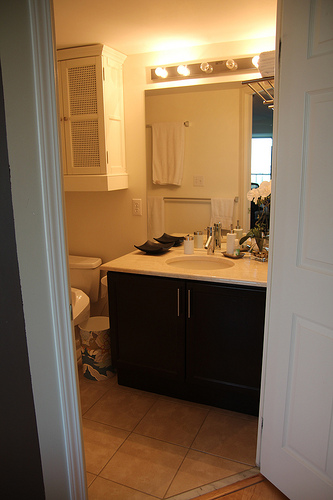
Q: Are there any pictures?
A: No, there are no pictures.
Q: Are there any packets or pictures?
A: No, there are no pictures or packets.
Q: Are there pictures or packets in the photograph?
A: No, there are no pictures or packets.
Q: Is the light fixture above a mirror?
A: Yes, the light fixture is above a mirror.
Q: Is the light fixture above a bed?
A: No, the light fixture is above a mirror.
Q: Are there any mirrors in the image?
A: Yes, there is a mirror.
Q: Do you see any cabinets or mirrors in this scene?
A: Yes, there is a mirror.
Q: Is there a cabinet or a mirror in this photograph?
A: Yes, there is a mirror.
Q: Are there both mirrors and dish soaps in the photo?
A: No, there is a mirror but no dish soaps.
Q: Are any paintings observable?
A: No, there are no paintings.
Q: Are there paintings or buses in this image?
A: No, there are no paintings or buses.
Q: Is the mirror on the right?
A: Yes, the mirror is on the right of the image.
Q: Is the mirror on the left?
A: No, the mirror is on the right of the image.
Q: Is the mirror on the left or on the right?
A: The mirror is on the right of the image.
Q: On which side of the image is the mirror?
A: The mirror is on the right of the image.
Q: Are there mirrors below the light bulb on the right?
A: Yes, there is a mirror below the bulb.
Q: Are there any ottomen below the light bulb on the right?
A: No, there is a mirror below the bulb.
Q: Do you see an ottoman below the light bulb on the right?
A: No, there is a mirror below the bulb.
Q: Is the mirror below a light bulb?
A: Yes, the mirror is below a light bulb.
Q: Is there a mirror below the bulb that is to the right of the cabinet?
A: Yes, there is a mirror below the light bulb.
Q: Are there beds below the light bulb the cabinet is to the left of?
A: No, there is a mirror below the light bulb.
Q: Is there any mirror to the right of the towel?
A: Yes, there is a mirror to the right of the towel.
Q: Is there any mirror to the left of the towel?
A: No, the mirror is to the right of the towel.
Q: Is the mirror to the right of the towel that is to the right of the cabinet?
A: Yes, the mirror is to the right of the towel.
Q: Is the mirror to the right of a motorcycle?
A: No, the mirror is to the right of the towel.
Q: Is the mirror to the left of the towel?
A: No, the mirror is to the right of the towel.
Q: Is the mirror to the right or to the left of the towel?
A: The mirror is to the right of the towel.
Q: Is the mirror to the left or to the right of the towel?
A: The mirror is to the right of the towel.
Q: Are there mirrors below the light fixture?
A: Yes, there is a mirror below the light fixture.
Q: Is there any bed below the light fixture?
A: No, there is a mirror below the light fixture.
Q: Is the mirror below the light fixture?
A: Yes, the mirror is below the light fixture.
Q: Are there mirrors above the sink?
A: Yes, there is a mirror above the sink.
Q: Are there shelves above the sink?
A: No, there is a mirror above the sink.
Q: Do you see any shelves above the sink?
A: No, there is a mirror above the sink.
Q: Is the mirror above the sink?
A: Yes, the mirror is above the sink.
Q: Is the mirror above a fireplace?
A: No, the mirror is above the sink.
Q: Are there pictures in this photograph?
A: No, there are no pictures.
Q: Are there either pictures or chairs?
A: No, there are no pictures or chairs.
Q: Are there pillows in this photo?
A: No, there are no pillows.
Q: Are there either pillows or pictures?
A: No, there are no pillows or pictures.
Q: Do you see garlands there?
A: No, there are no garlands.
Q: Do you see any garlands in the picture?
A: No, there are no garlands.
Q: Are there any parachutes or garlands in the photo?
A: No, there are no garlands or parachutes.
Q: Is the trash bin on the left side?
A: Yes, the trash bin is on the left of the image.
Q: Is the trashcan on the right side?
A: No, the trashcan is on the left of the image.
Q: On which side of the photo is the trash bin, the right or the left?
A: The trash bin is on the left of the image.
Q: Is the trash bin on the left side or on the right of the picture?
A: The trash bin is on the left of the image.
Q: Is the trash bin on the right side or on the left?
A: The trash bin is on the left of the image.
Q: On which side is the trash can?
A: The trash can is on the left of the image.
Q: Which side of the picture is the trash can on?
A: The trash can is on the left of the image.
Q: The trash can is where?
A: The trash can is on the floor.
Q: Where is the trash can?
A: The trash can is on the floor.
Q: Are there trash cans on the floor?
A: Yes, there is a trash can on the floor.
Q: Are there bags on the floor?
A: No, there is a trash can on the floor.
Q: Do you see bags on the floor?
A: No, there is a trash can on the floor.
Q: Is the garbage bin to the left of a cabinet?
A: Yes, the garbage bin is to the left of a cabinet.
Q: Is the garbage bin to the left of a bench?
A: No, the garbage bin is to the left of a cabinet.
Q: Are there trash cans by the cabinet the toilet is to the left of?
A: Yes, there is a trash can by the cabinet.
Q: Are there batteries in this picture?
A: No, there are no batteries.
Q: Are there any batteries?
A: No, there are no batteries.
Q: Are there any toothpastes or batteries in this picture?
A: No, there are no batteries or toothpastes.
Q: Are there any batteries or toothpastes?
A: No, there are no batteries or toothpastes.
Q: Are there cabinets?
A: Yes, there is a cabinet.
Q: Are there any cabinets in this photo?
A: Yes, there is a cabinet.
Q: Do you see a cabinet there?
A: Yes, there is a cabinet.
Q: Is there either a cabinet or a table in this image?
A: Yes, there is a cabinet.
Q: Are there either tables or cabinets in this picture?
A: Yes, there is a cabinet.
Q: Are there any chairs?
A: No, there are no chairs.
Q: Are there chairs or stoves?
A: No, there are no chairs or stoves.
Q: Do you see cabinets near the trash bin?
A: Yes, there is a cabinet near the trash bin.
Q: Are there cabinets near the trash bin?
A: Yes, there is a cabinet near the trash bin.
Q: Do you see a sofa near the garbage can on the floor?
A: No, there is a cabinet near the trash bin.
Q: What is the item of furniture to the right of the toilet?
A: The piece of furniture is a cabinet.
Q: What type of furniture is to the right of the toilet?
A: The piece of furniture is a cabinet.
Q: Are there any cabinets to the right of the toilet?
A: Yes, there is a cabinet to the right of the toilet.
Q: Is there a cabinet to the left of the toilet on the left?
A: No, the cabinet is to the right of the toilet.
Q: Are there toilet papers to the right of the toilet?
A: No, there is a cabinet to the right of the toilet.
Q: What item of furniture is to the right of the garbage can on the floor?
A: The piece of furniture is a cabinet.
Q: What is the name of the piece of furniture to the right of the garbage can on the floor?
A: The piece of furniture is a cabinet.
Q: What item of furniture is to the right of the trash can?
A: The piece of furniture is a cabinet.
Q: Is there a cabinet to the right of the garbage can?
A: Yes, there is a cabinet to the right of the garbage can.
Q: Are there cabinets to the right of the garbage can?
A: Yes, there is a cabinet to the right of the garbage can.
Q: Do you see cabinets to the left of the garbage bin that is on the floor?
A: No, the cabinet is to the right of the garbage bin.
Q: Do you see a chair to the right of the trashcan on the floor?
A: No, there is a cabinet to the right of the trashcan.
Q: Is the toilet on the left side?
A: Yes, the toilet is on the left of the image.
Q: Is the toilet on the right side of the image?
A: No, the toilet is on the left of the image.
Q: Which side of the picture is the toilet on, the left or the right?
A: The toilet is on the left of the image.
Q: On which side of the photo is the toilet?
A: The toilet is on the left of the image.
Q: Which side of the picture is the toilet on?
A: The toilet is on the left of the image.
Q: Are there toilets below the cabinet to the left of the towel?
A: Yes, there is a toilet below the cabinet.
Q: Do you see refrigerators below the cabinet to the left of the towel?
A: No, there is a toilet below the cabinet.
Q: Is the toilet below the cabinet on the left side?
A: Yes, the toilet is below the cabinet.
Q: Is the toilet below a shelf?
A: No, the toilet is below the cabinet.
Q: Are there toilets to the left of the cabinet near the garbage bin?
A: Yes, there is a toilet to the left of the cabinet.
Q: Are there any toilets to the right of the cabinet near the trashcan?
A: No, the toilet is to the left of the cabinet.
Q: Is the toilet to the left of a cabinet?
A: Yes, the toilet is to the left of a cabinet.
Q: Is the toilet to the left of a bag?
A: No, the toilet is to the left of a cabinet.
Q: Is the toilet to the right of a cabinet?
A: No, the toilet is to the left of a cabinet.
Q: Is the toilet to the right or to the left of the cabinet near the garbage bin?
A: The toilet is to the left of the cabinet.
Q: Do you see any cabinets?
A: Yes, there is a cabinet.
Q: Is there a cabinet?
A: Yes, there is a cabinet.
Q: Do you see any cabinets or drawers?
A: Yes, there is a cabinet.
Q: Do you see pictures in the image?
A: No, there are no pictures.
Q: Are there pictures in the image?
A: No, there are no pictures.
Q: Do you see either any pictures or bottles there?
A: No, there are no pictures or bottles.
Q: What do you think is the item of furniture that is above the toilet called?
A: The piece of furniture is a cabinet.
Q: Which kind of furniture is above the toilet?
A: The piece of furniture is a cabinet.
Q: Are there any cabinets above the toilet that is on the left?
A: Yes, there is a cabinet above the toilet.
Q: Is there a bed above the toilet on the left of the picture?
A: No, there is a cabinet above the toilet.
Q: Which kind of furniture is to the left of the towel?
A: The piece of furniture is a cabinet.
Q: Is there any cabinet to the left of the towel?
A: Yes, there is a cabinet to the left of the towel.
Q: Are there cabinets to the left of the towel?
A: Yes, there is a cabinet to the left of the towel.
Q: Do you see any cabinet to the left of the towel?
A: Yes, there is a cabinet to the left of the towel.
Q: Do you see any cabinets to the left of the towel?
A: Yes, there is a cabinet to the left of the towel.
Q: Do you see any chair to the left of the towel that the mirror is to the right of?
A: No, there is a cabinet to the left of the towel.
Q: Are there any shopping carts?
A: No, there are no shopping carts.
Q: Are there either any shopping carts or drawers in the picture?
A: No, there are no shopping carts or drawers.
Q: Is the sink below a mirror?
A: Yes, the sink is below a mirror.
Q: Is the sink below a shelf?
A: No, the sink is below a mirror.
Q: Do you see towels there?
A: Yes, there is a towel.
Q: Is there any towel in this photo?
A: Yes, there is a towel.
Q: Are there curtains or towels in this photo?
A: Yes, there is a towel.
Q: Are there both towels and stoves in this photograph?
A: No, there is a towel but no stoves.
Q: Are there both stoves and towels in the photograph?
A: No, there is a towel but no stoves.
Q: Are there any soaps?
A: No, there are no soaps.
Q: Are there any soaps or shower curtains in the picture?
A: No, there are no soaps or shower curtains.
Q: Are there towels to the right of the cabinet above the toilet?
A: Yes, there is a towel to the right of the cabinet.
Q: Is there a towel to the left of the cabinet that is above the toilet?
A: No, the towel is to the right of the cabinet.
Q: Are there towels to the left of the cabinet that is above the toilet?
A: No, the towel is to the right of the cabinet.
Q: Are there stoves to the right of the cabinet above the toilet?
A: No, there is a towel to the right of the cabinet.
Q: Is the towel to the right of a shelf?
A: No, the towel is to the right of a cabinet.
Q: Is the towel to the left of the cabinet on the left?
A: No, the towel is to the right of the cabinet.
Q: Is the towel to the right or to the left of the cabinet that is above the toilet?
A: The towel is to the right of the cabinet.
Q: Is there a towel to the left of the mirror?
A: Yes, there is a towel to the left of the mirror.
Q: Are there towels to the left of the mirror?
A: Yes, there is a towel to the left of the mirror.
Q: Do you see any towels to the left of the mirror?
A: Yes, there is a towel to the left of the mirror.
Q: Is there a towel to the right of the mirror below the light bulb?
A: No, the towel is to the left of the mirror.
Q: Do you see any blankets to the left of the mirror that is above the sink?
A: No, there is a towel to the left of the mirror.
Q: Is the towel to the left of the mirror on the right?
A: Yes, the towel is to the left of the mirror.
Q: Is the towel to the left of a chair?
A: No, the towel is to the left of the mirror.